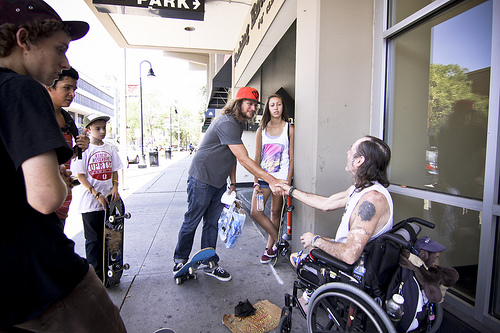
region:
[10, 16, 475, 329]
picture taken outside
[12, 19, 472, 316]
picture taken during the day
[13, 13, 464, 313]
teenagers are standing with skateboards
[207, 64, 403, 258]
a man shakes another man's hand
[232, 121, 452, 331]
a man in a wheel chair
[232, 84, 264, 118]
the man is smiling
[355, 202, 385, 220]
the man has a tattoo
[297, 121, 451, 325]
the man is in a wheel chair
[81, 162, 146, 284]
a boy is holding a skateboard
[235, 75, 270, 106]
the boy wears a hat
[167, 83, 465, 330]
A man in a wheel chair shaking hands with a skateboarder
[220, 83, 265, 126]
A man wearing a red cap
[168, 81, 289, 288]
A man standing on his skateboard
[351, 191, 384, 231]
A tattoo on a shoulder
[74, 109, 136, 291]
A boy holding a skateboard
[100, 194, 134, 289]
The bottom of a skateboard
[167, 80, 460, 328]
Two men shaking hands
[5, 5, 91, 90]
A man's head in a cap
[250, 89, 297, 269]
A woman watching a handshake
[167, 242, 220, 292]
A skateboard flipped up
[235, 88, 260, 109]
His hat is orange.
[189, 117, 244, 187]
The shirt is grey.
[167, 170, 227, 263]
he is wearing jeans.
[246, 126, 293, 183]
Her shirt is white.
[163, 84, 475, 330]
They are shaking hands.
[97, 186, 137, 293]
His skateboard is black.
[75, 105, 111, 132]
His hat is black.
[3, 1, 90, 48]
His hat is black.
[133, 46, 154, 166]
The light post is off.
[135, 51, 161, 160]
The light is grey.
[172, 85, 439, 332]
Man and boy shaking hands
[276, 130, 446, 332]
Man in a wheelchair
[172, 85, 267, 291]
Boy with a skateboard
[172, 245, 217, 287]
Skateboard tilted with front wheels off the ground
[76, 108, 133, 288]
Boy holding a skateboard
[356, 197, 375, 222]
Tattoo on man's arm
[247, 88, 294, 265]
Girl leaning on building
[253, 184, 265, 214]
Plastic water bottle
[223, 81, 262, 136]
Boy with red cap and long brown hair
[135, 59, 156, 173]
Street light at the curb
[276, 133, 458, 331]
The man is in a wheelchair.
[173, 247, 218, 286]
The skateboard is blue on the bottom.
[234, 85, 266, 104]
The baseball hat is red.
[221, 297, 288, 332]
A cardboard sign is on the floor.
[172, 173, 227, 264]
The man is wearing jeans.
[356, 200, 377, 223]
The man has a tattoo.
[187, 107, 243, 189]
The shirt is dark gray.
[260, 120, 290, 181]
The girl is wearing a tank top.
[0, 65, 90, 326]
The t-shirt is black.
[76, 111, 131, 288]
The boy holds a skateboard.